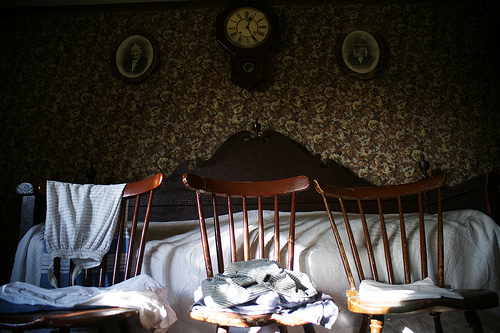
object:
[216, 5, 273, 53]
clock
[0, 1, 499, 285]
wall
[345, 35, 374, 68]
man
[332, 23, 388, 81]
portrait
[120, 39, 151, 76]
lady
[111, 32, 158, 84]
portrait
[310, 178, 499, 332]
wooden chair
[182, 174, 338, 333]
chair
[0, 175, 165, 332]
chair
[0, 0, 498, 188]
wall paper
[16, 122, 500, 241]
head board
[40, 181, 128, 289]
garment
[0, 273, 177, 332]
clothing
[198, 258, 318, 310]
chothes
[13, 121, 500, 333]
bed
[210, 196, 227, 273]
wooden rod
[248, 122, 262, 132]
wooden ball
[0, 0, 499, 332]
room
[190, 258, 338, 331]
pile of clothing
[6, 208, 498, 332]
bedspread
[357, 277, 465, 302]
towel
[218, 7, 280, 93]
old clock